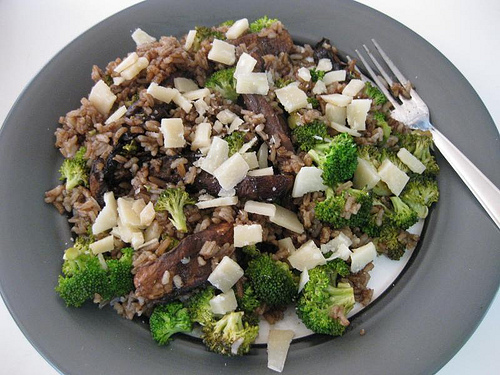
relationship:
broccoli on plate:
[286, 119, 410, 228] [31, 18, 484, 351]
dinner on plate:
[48, 19, 441, 365] [31, 18, 484, 351]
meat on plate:
[122, 219, 249, 305] [31, 18, 484, 351]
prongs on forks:
[340, 36, 432, 131] [340, 37, 484, 217]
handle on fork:
[423, 115, 481, 225] [342, 32, 484, 231]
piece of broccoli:
[282, 261, 375, 339] [293, 255, 365, 341]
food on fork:
[380, 65, 413, 109] [347, 40, 485, 239]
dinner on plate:
[48, 19, 441, 365] [18, 8, 483, 333]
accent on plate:
[387, 264, 422, 309] [18, 8, 483, 333]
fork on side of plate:
[342, 32, 484, 231] [2, 2, 471, 370]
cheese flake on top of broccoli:
[203, 254, 250, 296] [237, 254, 308, 315]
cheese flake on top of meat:
[203, 254, 250, 296] [131, 221, 233, 299]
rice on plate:
[145, 41, 199, 79] [2, 2, 471, 370]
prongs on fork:
[340, 33, 435, 132] [344, 37, 499, 232]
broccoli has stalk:
[295, 266, 365, 341] [328, 279, 360, 309]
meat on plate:
[122, 219, 249, 305] [2, 2, 471, 370]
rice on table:
[65, 98, 195, 206] [1, 3, 483, 372]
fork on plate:
[344, 37, 499, 232] [2, 2, 471, 370]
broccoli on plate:
[302, 125, 451, 248] [2, 2, 471, 370]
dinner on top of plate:
[48, 19, 441, 365] [2, 2, 471, 370]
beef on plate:
[245, 93, 299, 156] [2, 2, 471, 370]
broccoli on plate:
[286, 114, 377, 233] [2, 2, 471, 370]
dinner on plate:
[48, 19, 441, 365] [2, 2, 471, 370]